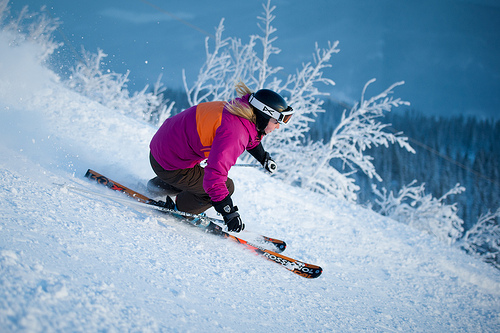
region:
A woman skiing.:
[84, 83, 323, 282]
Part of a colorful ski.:
[275, 253, 322, 278]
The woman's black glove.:
[216, 198, 246, 233]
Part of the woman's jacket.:
[170, 126, 190, 154]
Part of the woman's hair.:
[225, 99, 253, 120]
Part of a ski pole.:
[153, 203, 203, 220]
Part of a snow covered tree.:
[350, 76, 415, 162]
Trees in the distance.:
[447, 118, 492, 148]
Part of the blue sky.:
[135, 10, 201, 47]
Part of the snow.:
[93, 233, 130, 283]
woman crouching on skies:
[81, 83, 324, 284]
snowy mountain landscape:
[11, 12, 496, 327]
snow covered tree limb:
[317, 67, 419, 214]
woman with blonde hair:
[223, 75, 298, 140]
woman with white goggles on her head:
[238, 82, 300, 131]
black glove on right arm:
[205, 194, 248, 235]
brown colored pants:
[148, 153, 240, 233]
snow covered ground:
[0, 30, 91, 245]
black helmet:
[243, 82, 295, 130]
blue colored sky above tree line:
[408, 30, 492, 156]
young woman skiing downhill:
[20, 12, 465, 303]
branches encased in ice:
[350, 71, 415, 151]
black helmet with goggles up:
[250, 86, 295, 121]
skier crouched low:
[82, 50, 322, 280]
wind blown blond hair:
[225, 76, 255, 121]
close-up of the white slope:
[0, 240, 190, 326]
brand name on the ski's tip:
[262, 246, 319, 281]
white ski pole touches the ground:
[50, 175, 116, 206]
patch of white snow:
[271, 292, 316, 327]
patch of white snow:
[366, 286, 403, 326]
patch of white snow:
[29, 116, 62, 152]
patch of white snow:
[106, 258, 143, 291]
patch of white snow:
[146, 271, 187, 309]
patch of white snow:
[293, 210, 332, 253]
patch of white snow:
[285, 198, 317, 228]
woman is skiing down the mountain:
[145, 80, 295, 233]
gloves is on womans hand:
[213, 192, 245, 232]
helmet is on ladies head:
[246, 87, 288, 137]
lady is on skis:
[149, 84, 293, 230]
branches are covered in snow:
[1, 0, 498, 263]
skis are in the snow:
[79, 170, 324, 280]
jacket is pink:
[149, 95, 264, 200]